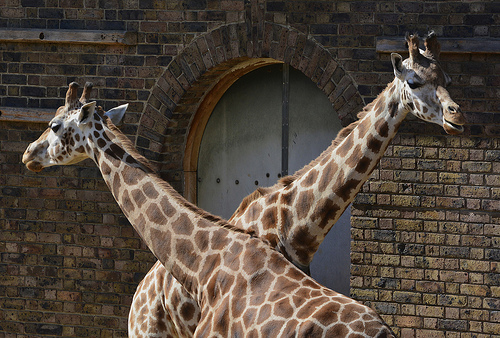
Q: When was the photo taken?
A: Daytime.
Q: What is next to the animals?
A: A building.